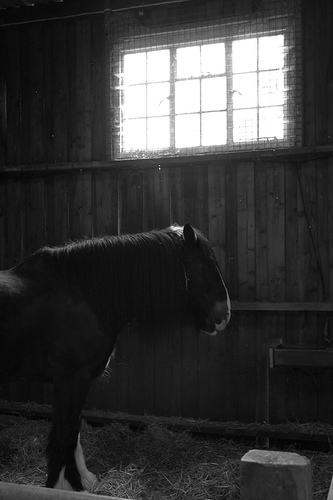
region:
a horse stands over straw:
[5, 212, 241, 489]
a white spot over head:
[136, 209, 239, 347]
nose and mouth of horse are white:
[207, 300, 238, 346]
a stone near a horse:
[17, 206, 322, 496]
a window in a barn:
[8, 5, 329, 494]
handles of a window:
[149, 77, 246, 114]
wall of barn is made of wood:
[5, 11, 329, 410]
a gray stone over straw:
[210, 436, 326, 493]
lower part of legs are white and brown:
[38, 409, 101, 496]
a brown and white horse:
[5, 215, 244, 490]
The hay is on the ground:
[120, 440, 212, 492]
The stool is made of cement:
[228, 446, 319, 498]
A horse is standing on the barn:
[18, 202, 266, 492]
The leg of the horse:
[37, 379, 105, 491]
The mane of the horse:
[69, 232, 198, 358]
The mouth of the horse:
[200, 307, 228, 339]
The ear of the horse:
[179, 221, 198, 250]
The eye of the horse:
[200, 250, 221, 276]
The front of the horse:
[86, 220, 242, 354]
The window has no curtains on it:
[101, 17, 311, 164]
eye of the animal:
[197, 251, 222, 279]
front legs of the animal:
[26, 377, 119, 494]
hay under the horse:
[159, 454, 219, 490]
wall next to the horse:
[133, 349, 228, 394]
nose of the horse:
[190, 290, 245, 341]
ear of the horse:
[175, 217, 201, 250]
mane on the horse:
[54, 229, 184, 324]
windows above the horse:
[79, 15, 321, 180]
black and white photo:
[24, 32, 320, 229]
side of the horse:
[2, 213, 274, 349]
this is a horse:
[23, 224, 220, 488]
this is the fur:
[111, 242, 146, 287]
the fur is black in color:
[117, 242, 157, 288]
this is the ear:
[181, 218, 198, 246]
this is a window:
[120, 44, 274, 143]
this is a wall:
[36, 112, 94, 194]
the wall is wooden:
[254, 176, 289, 232]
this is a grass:
[145, 411, 172, 484]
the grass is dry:
[148, 426, 196, 487]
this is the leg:
[48, 383, 90, 482]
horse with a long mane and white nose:
[22, 215, 257, 363]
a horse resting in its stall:
[6, 212, 241, 496]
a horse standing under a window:
[66, 19, 310, 352]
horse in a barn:
[13, 20, 289, 344]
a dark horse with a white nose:
[25, 217, 238, 382]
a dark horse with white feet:
[14, 218, 241, 496]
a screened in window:
[96, 15, 311, 166]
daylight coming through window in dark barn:
[107, 23, 297, 160]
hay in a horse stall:
[99, 409, 244, 495]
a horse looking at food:
[7, 221, 247, 392]